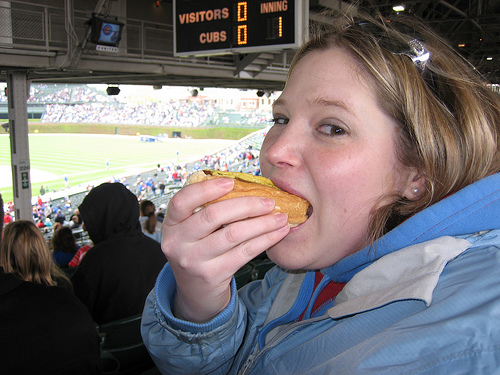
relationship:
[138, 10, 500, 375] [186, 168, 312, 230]
woman eating hot dog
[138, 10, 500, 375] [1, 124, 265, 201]
woman at baseball game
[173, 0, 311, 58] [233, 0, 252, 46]
screen with scores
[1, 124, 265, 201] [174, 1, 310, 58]
baseball game has scoreboard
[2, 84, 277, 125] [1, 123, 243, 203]
spectators across diamond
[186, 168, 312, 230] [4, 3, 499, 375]
hot dog at stadium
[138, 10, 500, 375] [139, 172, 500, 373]
woman wearing jacket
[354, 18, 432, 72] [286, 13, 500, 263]
sunglasses are in hair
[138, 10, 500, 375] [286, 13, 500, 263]
woman has hair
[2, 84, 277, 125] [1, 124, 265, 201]
spectators at baseball game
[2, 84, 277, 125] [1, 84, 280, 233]
spectators are in background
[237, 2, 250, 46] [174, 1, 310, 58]
number on scoreboard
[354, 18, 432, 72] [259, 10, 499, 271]
sunglasses on head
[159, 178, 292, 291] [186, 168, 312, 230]
hand holding hot dog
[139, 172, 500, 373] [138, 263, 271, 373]
jacket has sleeve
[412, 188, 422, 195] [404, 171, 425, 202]
earring in earlobe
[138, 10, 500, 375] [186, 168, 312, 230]
woman holding hot dog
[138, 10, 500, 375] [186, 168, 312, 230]
woman biting hot dog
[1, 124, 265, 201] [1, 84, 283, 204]
baseball game in distance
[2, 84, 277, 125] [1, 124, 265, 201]
spectators watch baseball game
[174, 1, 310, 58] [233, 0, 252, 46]
scoreboard displays scores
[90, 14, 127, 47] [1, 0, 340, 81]
tv on wall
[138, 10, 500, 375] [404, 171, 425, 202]
woman has earlobe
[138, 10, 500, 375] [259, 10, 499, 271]
woman has head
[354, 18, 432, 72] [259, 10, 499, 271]
sunglasses sitting on head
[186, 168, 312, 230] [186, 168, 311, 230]
hot dog has bun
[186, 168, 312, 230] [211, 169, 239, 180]
hot dog has mustard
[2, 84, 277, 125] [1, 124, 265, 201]
spectators watching baseball game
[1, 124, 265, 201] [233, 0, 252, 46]
baseball game has scores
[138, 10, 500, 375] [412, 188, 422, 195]
woman has earring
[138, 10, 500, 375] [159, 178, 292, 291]
woman has hand